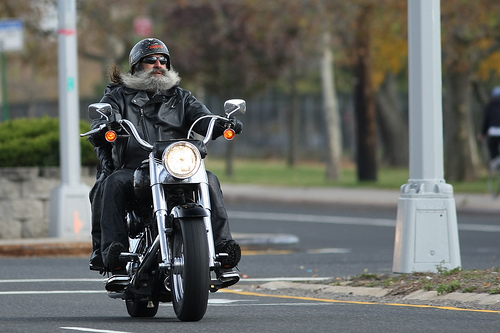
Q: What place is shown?
A: It is a street.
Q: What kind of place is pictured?
A: It is a street.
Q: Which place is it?
A: It is a street.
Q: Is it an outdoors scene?
A: Yes, it is outdoors.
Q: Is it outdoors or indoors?
A: It is outdoors.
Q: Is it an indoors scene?
A: No, it is outdoors.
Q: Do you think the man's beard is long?
A: Yes, the beard is long.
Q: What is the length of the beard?
A: The beard is long.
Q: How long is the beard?
A: The beard is long.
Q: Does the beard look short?
A: No, the beard is long.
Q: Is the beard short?
A: No, the beard is long.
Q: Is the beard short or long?
A: The beard is long.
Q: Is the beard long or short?
A: The beard is long.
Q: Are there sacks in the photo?
A: No, there are no sacks.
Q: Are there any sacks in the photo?
A: No, there are no sacks.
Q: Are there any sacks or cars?
A: No, there are no sacks or cars.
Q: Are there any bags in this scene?
A: No, there are no bags.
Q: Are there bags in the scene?
A: No, there are no bags.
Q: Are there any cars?
A: No, there are no cars.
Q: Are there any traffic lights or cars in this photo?
A: No, there are no cars or traffic lights.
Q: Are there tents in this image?
A: No, there are no tents.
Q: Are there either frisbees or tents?
A: No, there are no tents or frisbees.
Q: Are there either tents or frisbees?
A: No, there are no tents or frisbees.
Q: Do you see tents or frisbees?
A: No, there are no tents or frisbees.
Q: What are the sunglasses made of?
A: The sunglasses are made of plastic.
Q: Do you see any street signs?
A: Yes, there is a street sign.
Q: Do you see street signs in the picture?
A: Yes, there is a street sign.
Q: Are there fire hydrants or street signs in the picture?
A: Yes, there is a street sign.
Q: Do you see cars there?
A: No, there are no cars.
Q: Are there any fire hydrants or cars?
A: No, there are no cars or fire hydrants.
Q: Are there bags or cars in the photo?
A: No, there are no cars or bags.